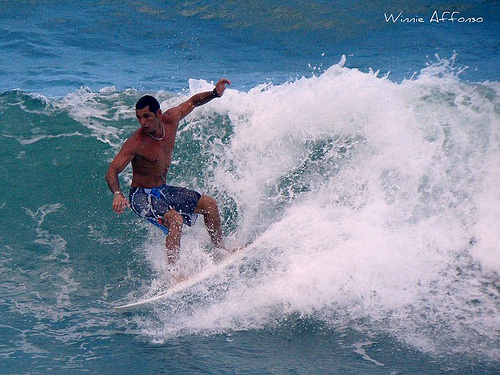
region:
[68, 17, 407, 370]
he is riding a wave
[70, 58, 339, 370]
he is riding a surfboard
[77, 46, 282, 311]
he is wearing boardshorts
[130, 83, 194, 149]
he is wearing a necklace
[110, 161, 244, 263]
his shorts are blue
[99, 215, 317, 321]
his board is white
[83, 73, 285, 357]
the water is splashing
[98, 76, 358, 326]
A man surfing on a surf board.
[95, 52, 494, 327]
The man is surfing a small wave.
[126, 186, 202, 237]
The man is wearing blue swim trunks.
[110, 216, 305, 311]
The surf board is white on the sides.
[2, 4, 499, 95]
Calm water is very blue.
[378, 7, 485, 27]
Photo by Winnie Affonso is declared in upper right corner.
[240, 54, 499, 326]
Wave is small with white cap.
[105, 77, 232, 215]
Man has no shirt on his body.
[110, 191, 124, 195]
Man is wearing a gold watch.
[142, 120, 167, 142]
Man is wearing a necklace around his neck.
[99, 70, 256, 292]
surfer is bent backward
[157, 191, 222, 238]
knees are bend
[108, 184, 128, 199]
a clock on wrist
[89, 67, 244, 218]
the arms of man are extended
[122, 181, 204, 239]
a short color dark and light blue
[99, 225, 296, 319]
a surfboard color white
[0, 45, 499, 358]
a wave is rolling in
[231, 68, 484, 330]
white foamy water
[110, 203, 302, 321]
a white surfboard under the surfer's feet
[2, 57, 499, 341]
a medium sized wave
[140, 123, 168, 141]
a necklace around the man's neck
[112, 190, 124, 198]
a watch on the man's right wrist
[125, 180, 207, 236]
a pair of blue and white swimming trunks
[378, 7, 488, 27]
a name written in the upper right corner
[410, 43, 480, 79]
water splashing up from the wave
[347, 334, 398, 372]
foam collecting in the ocean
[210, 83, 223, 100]
a black band on the man's left wrist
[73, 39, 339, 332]
The surfer rides the wave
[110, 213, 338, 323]
The surferboard is white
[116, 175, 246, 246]
The shorts are blue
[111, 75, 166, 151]
The surfer has brown hair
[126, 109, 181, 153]
The surfer wears a necklace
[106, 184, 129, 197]
The surfer wears a watch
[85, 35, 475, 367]
The water is rough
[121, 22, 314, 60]
The water is blue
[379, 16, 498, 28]
The print is signed by the artist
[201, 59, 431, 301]
The waves are white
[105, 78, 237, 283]
tanned young man on a surf board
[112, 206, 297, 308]
surf board under young man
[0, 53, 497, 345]
wave being ridden on by surfer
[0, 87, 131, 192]
curl in the left top of the wave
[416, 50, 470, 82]
splash going over the right side of the wave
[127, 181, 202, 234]
blue shorts on legs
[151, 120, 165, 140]
necklace around man's neck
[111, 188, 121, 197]
bracelet around wrist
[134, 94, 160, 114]
dark hair on head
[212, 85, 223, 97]
black watch on man's wrist